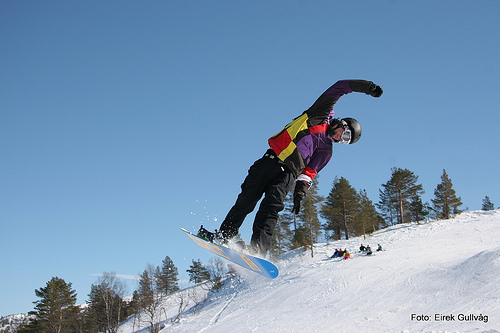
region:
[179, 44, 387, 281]
snow boarder flying through the air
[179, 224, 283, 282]
blue and yellow snow board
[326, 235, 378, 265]
group of skiers sitting in the snow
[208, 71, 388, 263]
man wearing black coat with multi colored blocks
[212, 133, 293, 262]
man wearing black snow pants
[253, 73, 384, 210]
man wearing black gloves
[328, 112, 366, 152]
man wearing helmet and goggles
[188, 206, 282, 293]
snow flying from snow board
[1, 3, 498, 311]
crystal blue clear sky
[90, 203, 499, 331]
white snow on mountain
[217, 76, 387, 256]
Athletic person in air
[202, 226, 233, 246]
Foot of athletic person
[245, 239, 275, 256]
Foot of athletic person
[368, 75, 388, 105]
Gloved hand of athletic person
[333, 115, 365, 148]
Head of athletic person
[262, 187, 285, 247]
Part of athlete's leg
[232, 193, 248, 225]
Part of athlete's leg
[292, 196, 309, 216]
gloved hand of athlete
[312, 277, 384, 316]
tracks on snowey slope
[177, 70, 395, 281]
A person is snowboarding.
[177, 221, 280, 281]
The board is blue and yellow.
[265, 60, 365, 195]
The jacket has black, red, yellow, purple, and white on it.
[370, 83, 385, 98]
Ther person is wearing a glove.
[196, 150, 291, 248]
The person is wearing black pants.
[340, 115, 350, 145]
The person is wearing goggles.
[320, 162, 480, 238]
Green trees are on the hillside.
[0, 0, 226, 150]
The sky is blue.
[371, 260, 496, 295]
The snow is white.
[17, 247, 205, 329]
Pine trees on a snowy hill.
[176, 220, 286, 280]
Man on a board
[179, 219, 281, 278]
Man is on a board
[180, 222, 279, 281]
Man on a snowboard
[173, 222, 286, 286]
Man is on a snowboard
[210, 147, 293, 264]
Man wearing pants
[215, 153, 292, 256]
Man is wearing pants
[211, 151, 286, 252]
Man wearing black pants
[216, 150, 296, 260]
Man is wearing black pants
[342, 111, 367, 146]
Man wearing a black helmet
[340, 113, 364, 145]
Man is wearing a black helmet